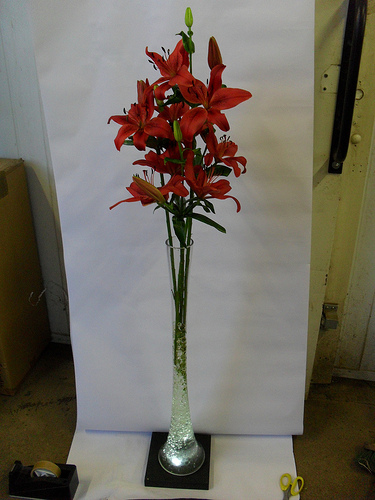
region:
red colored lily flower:
[176, 63, 252, 135]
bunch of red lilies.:
[103, 6, 255, 475]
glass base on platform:
[157, 234, 206, 472]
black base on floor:
[142, 428, 214, 491]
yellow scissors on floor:
[277, 475, 302, 499]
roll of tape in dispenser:
[8, 459, 79, 498]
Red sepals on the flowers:
[118, 51, 227, 157]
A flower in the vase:
[111, 37, 237, 334]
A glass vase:
[165, 336, 204, 438]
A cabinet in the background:
[10, 228, 50, 356]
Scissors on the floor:
[266, 469, 304, 496]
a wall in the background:
[316, 153, 351, 270]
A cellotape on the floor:
[10, 456, 67, 480]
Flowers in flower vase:
[110, 4, 225, 477]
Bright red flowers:
[106, 51, 250, 228]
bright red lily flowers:
[111, 24, 251, 256]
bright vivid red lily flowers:
[113, 40, 249, 225]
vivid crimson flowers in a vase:
[105, 32, 251, 238]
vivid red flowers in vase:
[110, 74, 246, 235]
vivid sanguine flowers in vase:
[102, 37, 249, 233]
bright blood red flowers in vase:
[102, 25, 256, 241]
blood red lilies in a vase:
[109, 14, 255, 236]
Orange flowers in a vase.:
[106, 6, 252, 231]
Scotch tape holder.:
[5, 460, 80, 499]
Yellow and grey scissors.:
[278, 471, 303, 498]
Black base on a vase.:
[143, 431, 211, 491]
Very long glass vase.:
[158, 237, 206, 478]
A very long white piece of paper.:
[26, 1, 312, 436]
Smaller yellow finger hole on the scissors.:
[277, 471, 291, 492]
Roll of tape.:
[27, 461, 59, 477]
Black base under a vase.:
[144, 432, 212, 489]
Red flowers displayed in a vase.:
[106, 6, 252, 489]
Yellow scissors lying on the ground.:
[278, 472, 303, 499]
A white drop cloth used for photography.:
[30, 3, 304, 499]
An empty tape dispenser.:
[8, 458, 79, 497]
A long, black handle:
[319, 0, 364, 174]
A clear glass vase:
[161, 235, 205, 473]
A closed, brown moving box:
[1, 158, 55, 391]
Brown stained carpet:
[1, 337, 373, 498]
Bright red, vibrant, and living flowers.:
[105, 7, 243, 235]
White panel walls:
[0, 0, 373, 381]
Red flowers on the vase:
[102, 60, 249, 208]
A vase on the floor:
[153, 329, 211, 459]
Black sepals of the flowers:
[154, 210, 217, 282]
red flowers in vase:
[104, 5, 258, 476]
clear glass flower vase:
[152, 232, 216, 482]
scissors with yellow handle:
[273, 469, 308, 499]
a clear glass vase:
[154, 234, 205, 476]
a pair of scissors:
[277, 472, 303, 499]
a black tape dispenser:
[5, 459, 77, 499]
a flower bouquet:
[103, 6, 251, 243]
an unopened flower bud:
[184, 5, 193, 26]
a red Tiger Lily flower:
[182, 151, 240, 211]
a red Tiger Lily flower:
[199, 127, 247, 177]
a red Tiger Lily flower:
[105, 79, 174, 151]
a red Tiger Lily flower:
[176, 66, 249, 142]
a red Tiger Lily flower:
[145, 41, 195, 101]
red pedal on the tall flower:
[203, 182, 234, 197]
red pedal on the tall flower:
[198, 193, 244, 214]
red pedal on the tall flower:
[107, 193, 153, 211]